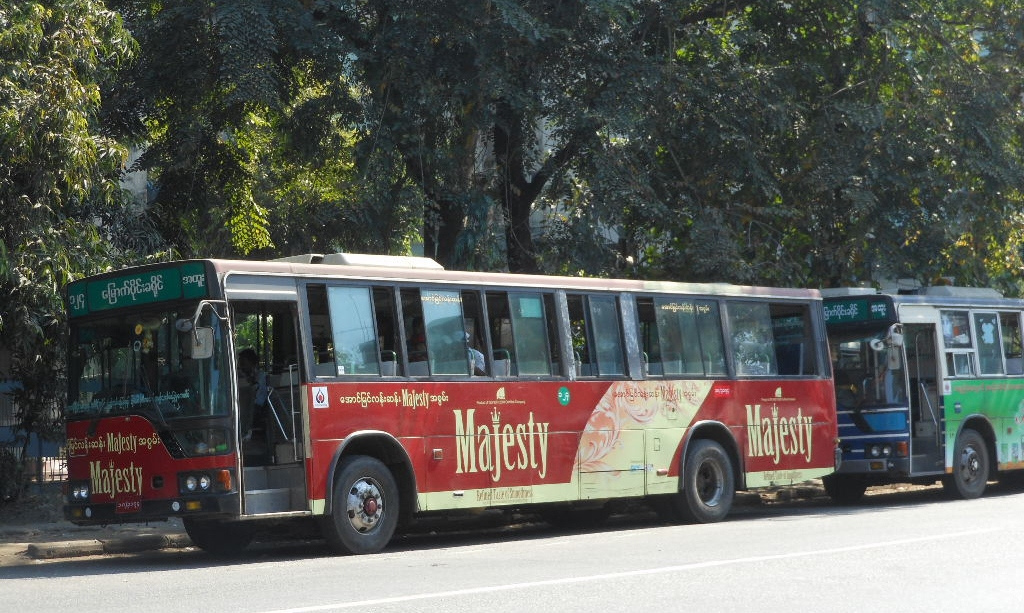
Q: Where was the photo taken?
A: At a bus stop.